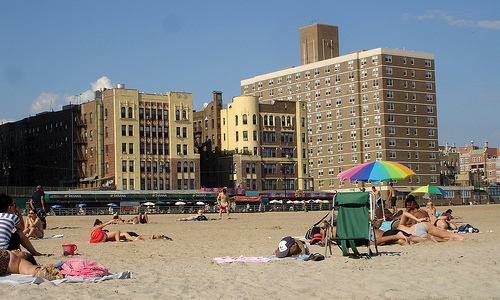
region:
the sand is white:
[216, 265, 254, 295]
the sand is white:
[246, 282, 261, 293]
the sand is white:
[226, 225, 309, 297]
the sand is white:
[230, 282, 240, 293]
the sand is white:
[245, 284, 255, 291]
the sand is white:
[263, 289, 279, 299]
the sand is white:
[236, 265, 306, 297]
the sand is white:
[213, 256, 248, 282]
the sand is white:
[233, 265, 241, 271]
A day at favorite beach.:
[10, 153, 484, 293]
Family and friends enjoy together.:
[308, 189, 488, 256]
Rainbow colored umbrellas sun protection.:
[335, 153, 453, 203]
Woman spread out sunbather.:
[0, 244, 55, 299]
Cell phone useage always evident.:
[17, 206, 53, 241]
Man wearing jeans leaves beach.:
[28, 180, 56, 231]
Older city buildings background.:
[84, 78, 319, 190]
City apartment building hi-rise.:
[302, 39, 443, 192]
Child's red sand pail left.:
[54, 233, 82, 259]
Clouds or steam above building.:
[14, 70, 125, 111]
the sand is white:
[278, 280, 314, 297]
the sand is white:
[283, 272, 349, 297]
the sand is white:
[322, 276, 364, 296]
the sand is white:
[275, 257, 332, 290]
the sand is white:
[253, 220, 400, 297]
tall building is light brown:
[240, 34, 437, 187]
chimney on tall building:
[290, 25, 342, 77]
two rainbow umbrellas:
[341, 141, 440, 244]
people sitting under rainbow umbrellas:
[365, 186, 447, 240]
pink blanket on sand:
[216, 246, 336, 266]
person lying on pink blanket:
[272, 218, 322, 269]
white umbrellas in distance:
[125, 197, 255, 218]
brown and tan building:
[126, 93, 313, 183]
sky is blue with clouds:
[17, 28, 119, 135]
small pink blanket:
[62, 251, 93, 280]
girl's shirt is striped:
[0, 204, 30, 252]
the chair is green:
[325, 165, 376, 250]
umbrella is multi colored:
[328, 149, 419, 191]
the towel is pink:
[49, 242, 123, 284]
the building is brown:
[244, 41, 446, 187]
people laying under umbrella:
[369, 190, 451, 251]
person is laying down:
[3, 242, 54, 295]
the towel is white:
[184, 242, 289, 287]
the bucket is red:
[50, 231, 89, 267]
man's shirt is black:
[23, 183, 53, 208]